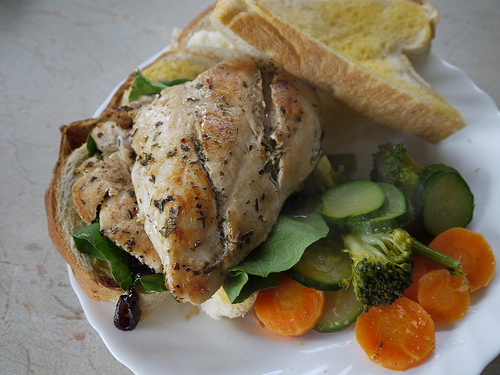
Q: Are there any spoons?
A: No, there are no spoons.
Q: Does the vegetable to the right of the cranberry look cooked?
A: Yes, the vegetable is cooked.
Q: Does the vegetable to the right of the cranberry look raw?
A: No, the vegetable is cooked.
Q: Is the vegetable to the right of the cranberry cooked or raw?
A: The vegetable is cooked.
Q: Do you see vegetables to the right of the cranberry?
A: Yes, there is a vegetable to the right of the cranberry.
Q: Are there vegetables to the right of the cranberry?
A: Yes, there is a vegetable to the right of the cranberry.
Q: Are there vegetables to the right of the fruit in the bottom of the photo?
A: Yes, there is a vegetable to the right of the cranberry.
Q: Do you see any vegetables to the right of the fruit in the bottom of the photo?
A: Yes, there is a vegetable to the right of the cranberry.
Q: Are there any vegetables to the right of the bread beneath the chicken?
A: Yes, there is a vegetable to the right of the bread.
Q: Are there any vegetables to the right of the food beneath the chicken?
A: Yes, there is a vegetable to the right of the bread.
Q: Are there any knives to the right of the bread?
A: No, there is a vegetable to the right of the bread.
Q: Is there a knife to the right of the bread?
A: No, there is a vegetable to the right of the bread.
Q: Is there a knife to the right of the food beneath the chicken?
A: No, there is a vegetable to the right of the bread.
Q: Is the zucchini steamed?
A: Yes, the zucchini is steamed.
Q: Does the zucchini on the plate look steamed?
A: Yes, the zucchini is steamed.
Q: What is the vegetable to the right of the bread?
A: The vegetable is a zucchini.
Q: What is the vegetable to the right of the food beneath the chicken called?
A: The vegetable is a zucchini.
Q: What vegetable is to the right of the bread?
A: The vegetable is a zucchini.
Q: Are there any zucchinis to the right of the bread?
A: Yes, there is a zucchini to the right of the bread.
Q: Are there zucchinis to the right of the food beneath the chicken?
A: Yes, there is a zucchini to the right of the bread.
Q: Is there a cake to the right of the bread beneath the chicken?
A: No, there is a zucchini to the right of the bread.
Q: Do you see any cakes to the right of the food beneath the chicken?
A: No, there is a zucchini to the right of the bread.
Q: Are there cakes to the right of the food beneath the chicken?
A: No, there is a zucchini to the right of the bread.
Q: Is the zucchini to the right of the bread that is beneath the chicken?
A: Yes, the zucchini is to the right of the bread.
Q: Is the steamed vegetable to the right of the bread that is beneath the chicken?
A: Yes, the zucchini is to the right of the bread.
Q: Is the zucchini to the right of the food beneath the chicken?
A: Yes, the zucchini is to the right of the bread.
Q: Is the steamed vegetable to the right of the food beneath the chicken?
A: Yes, the zucchini is to the right of the bread.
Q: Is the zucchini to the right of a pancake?
A: No, the zucchini is to the right of the bread.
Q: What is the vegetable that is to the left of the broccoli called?
A: The vegetable is a zucchini.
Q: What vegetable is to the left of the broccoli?
A: The vegetable is a zucchini.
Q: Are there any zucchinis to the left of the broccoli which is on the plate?
A: Yes, there is a zucchini to the left of the broccoli.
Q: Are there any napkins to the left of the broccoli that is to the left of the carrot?
A: No, there is a zucchini to the left of the broccoli.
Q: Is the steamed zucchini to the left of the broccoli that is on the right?
A: Yes, the zucchini is to the left of the broccoli.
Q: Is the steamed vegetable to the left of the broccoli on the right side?
A: Yes, the zucchini is to the left of the broccoli.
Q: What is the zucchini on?
A: The zucchini is on the plate.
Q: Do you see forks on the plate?
A: No, there is a zucchini on the plate.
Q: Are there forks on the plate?
A: No, there is a zucchini on the plate.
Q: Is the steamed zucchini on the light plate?
A: Yes, the zucchini is on the plate.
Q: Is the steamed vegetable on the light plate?
A: Yes, the zucchini is on the plate.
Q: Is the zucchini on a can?
A: No, the zucchini is on the plate.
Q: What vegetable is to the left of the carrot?
A: The vegetable is a zucchini.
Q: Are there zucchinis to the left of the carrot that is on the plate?
A: Yes, there is a zucchini to the left of the carrot.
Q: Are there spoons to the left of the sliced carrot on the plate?
A: No, there is a zucchini to the left of the carrot.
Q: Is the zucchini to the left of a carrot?
A: Yes, the zucchini is to the left of a carrot.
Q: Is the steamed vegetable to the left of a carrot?
A: Yes, the zucchini is to the left of a carrot.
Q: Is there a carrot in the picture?
A: Yes, there is a carrot.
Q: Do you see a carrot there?
A: Yes, there is a carrot.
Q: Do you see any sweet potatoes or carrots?
A: Yes, there is a carrot.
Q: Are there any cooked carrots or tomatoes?
A: Yes, there is a cooked carrot.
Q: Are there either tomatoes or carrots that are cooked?
A: Yes, the carrot is cooked.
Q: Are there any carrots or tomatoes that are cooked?
A: Yes, the carrot is cooked.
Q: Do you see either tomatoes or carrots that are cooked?
A: Yes, the carrot is cooked.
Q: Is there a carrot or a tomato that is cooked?
A: Yes, the carrot is cooked.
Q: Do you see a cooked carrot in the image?
A: Yes, there is a cooked carrot.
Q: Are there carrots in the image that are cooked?
A: Yes, there is a carrot that is cooked.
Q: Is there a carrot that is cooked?
A: Yes, there is a carrot that is cooked.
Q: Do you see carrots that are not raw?
A: Yes, there is a cooked carrot.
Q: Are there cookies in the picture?
A: No, there are no cookies.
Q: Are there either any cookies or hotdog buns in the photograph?
A: No, there are no cookies or hotdog buns.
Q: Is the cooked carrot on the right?
A: Yes, the carrot is on the right of the image.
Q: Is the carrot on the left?
A: No, the carrot is on the right of the image.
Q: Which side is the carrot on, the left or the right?
A: The carrot is on the right of the image.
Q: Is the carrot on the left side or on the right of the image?
A: The carrot is on the right of the image.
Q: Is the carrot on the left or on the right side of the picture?
A: The carrot is on the right of the image.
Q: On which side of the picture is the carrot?
A: The carrot is on the right of the image.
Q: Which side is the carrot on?
A: The carrot is on the right of the image.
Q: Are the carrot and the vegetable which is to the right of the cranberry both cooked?
A: Yes, both the carrot and the vegetable are cooked.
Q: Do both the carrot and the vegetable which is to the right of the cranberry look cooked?
A: Yes, both the carrot and the vegetable are cooked.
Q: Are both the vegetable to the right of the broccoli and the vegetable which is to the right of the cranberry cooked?
A: Yes, both the carrot and the vegetable are cooked.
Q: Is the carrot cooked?
A: Yes, the carrot is cooked.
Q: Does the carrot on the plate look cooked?
A: Yes, the carrot is cooked.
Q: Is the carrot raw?
A: No, the carrot is cooked.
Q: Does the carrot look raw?
A: No, the carrot is cooked.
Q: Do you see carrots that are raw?
A: No, there is a carrot but it is cooked.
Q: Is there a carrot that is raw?
A: No, there is a carrot but it is cooked.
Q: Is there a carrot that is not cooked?
A: No, there is a carrot but it is cooked.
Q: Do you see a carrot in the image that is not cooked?
A: No, there is a carrot but it is cooked.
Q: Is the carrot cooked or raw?
A: The carrot is cooked.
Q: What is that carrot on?
A: The carrot is on the plate.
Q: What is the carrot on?
A: The carrot is on the plate.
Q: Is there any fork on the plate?
A: No, there is a carrot on the plate.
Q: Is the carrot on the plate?
A: Yes, the carrot is on the plate.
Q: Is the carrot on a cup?
A: No, the carrot is on the plate.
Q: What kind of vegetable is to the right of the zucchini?
A: The vegetable is a carrot.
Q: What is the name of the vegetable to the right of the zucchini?
A: The vegetable is a carrot.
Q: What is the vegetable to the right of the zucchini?
A: The vegetable is a carrot.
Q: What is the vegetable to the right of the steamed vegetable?
A: The vegetable is a carrot.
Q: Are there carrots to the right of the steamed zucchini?
A: Yes, there is a carrot to the right of the zucchini.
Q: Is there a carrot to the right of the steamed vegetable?
A: Yes, there is a carrot to the right of the zucchini.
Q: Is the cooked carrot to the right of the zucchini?
A: Yes, the carrot is to the right of the zucchini.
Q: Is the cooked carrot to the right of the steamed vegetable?
A: Yes, the carrot is to the right of the zucchini.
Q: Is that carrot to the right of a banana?
A: No, the carrot is to the right of the zucchini.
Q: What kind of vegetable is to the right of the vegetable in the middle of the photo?
A: The vegetable is a carrot.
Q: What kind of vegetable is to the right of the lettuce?
A: The vegetable is a carrot.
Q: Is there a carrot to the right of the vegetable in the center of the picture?
A: Yes, there is a carrot to the right of the lettuce.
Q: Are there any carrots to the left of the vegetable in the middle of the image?
A: No, the carrot is to the right of the lettuce.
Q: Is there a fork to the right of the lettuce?
A: No, there is a carrot to the right of the lettuce.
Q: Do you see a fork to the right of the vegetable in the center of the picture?
A: No, there is a carrot to the right of the lettuce.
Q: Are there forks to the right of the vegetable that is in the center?
A: No, there is a carrot to the right of the lettuce.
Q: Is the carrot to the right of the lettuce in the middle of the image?
A: Yes, the carrot is to the right of the lettuce.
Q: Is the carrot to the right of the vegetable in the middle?
A: Yes, the carrot is to the right of the lettuce.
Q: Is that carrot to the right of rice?
A: No, the carrot is to the right of the lettuce.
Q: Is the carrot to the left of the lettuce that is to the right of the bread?
A: No, the carrot is to the right of the lettuce.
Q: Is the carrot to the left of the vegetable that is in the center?
A: No, the carrot is to the right of the lettuce.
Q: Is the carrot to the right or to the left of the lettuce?
A: The carrot is to the right of the lettuce.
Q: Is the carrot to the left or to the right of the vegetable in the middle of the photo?
A: The carrot is to the right of the lettuce.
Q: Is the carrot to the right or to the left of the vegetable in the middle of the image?
A: The carrot is to the right of the lettuce.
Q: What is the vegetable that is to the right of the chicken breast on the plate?
A: The vegetable is a carrot.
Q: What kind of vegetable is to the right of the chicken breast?
A: The vegetable is a carrot.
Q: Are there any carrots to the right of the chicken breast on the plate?
A: Yes, there is a carrot to the right of the chicken breast.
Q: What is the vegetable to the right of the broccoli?
A: The vegetable is a carrot.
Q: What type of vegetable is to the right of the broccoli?
A: The vegetable is a carrot.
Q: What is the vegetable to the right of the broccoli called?
A: The vegetable is a carrot.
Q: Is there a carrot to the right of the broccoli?
A: Yes, there is a carrot to the right of the broccoli.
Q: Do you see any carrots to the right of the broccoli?
A: Yes, there is a carrot to the right of the broccoli.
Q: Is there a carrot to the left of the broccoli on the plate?
A: No, the carrot is to the right of the broccoli.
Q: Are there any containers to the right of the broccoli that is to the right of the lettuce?
A: No, there is a carrot to the right of the broccoli.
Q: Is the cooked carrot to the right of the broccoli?
A: Yes, the carrot is to the right of the broccoli.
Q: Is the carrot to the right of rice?
A: No, the carrot is to the right of the broccoli.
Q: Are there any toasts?
A: Yes, there is a toast.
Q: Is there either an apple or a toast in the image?
A: Yes, there is a toast.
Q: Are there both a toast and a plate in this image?
A: Yes, there are both a toast and a plate.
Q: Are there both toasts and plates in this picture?
A: Yes, there are both a toast and a plate.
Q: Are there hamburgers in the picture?
A: No, there are no hamburgers.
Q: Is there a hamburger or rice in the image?
A: No, there are no hamburgers or rice.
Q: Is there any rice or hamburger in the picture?
A: No, there are no hamburgers or rice.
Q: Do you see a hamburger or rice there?
A: No, there are no hamburgers or rice.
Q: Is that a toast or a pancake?
A: That is a toast.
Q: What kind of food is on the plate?
A: The food is a toast.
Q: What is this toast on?
A: The toast is on the plate.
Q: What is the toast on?
A: The toast is on the plate.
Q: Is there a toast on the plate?
A: Yes, there is a toast on the plate.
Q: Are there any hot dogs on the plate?
A: No, there is a toast on the plate.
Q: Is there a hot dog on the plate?
A: No, there is a toast on the plate.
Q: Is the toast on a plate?
A: Yes, the toast is on a plate.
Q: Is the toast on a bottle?
A: No, the toast is on a plate.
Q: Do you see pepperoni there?
A: No, there is no pepperoni.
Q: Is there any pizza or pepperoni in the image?
A: No, there are no pepperoni or pizzas.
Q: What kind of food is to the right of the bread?
A: The food is chicken breast.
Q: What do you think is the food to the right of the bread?
A: The food is chicken breast.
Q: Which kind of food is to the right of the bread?
A: The food is chicken breast.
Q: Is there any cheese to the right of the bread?
A: No, there is chicken breast to the right of the bread.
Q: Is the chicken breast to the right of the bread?
A: Yes, the chicken breast is to the right of the bread.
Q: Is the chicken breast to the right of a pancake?
A: No, the chicken breast is to the right of the bread.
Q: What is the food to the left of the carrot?
A: The food is chicken breast.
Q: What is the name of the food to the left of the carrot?
A: The food is chicken breast.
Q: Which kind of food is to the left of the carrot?
A: The food is chicken breast.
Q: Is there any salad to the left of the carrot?
A: No, there is chicken breast to the left of the carrot.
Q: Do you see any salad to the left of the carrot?
A: No, there is chicken breast to the left of the carrot.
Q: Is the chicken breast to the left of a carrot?
A: Yes, the chicken breast is to the left of a carrot.